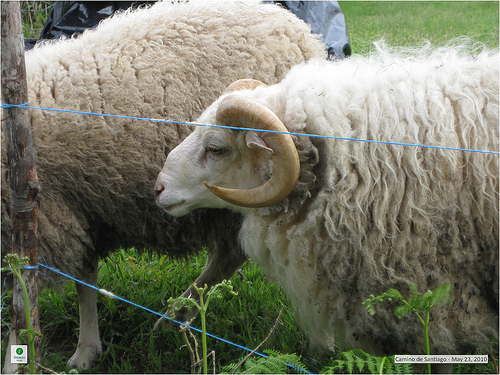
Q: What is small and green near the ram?
A: A weed.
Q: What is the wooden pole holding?
A: Blue rope.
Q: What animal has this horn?
A: A ram.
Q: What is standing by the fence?
A: Sheep.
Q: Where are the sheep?
A: By the fence.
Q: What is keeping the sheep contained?
A: A fence.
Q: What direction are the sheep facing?
A: Left.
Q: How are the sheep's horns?
A: They are brown.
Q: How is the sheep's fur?
A: Matted.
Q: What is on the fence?
A: A wooden pole.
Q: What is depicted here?
A: A tan ram horn.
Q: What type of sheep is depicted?
A: A large white wooly sheep.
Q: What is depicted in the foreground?
A: A white wooly sheep.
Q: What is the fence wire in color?
A: Blue.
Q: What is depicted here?
A: A blue fence wire.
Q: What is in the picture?
A: Two sheep side by side.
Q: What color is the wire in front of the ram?
A: Blue.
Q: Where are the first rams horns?
A: On his head.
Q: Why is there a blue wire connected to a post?
A: To keep the rams in.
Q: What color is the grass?
A: Green.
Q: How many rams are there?
A: Two.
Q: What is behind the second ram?
A: A black bag.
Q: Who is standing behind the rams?
A: No one.